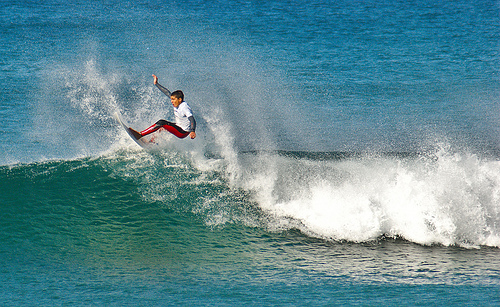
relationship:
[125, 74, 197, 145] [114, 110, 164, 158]
man riding board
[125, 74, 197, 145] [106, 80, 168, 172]
man on board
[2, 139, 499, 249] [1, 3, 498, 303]
wave in ocean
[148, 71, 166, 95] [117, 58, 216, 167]
right hand of surfer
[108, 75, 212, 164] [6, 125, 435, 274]
surfer on a wave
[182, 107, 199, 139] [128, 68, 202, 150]
arm of surfer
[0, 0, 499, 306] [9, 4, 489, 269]
wave in ocean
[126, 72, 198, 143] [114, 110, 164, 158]
surfer has board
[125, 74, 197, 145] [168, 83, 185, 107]
man has head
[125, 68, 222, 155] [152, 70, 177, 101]
man has arm